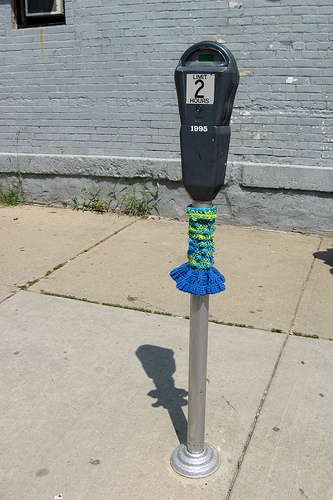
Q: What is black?
A: Parking meter.